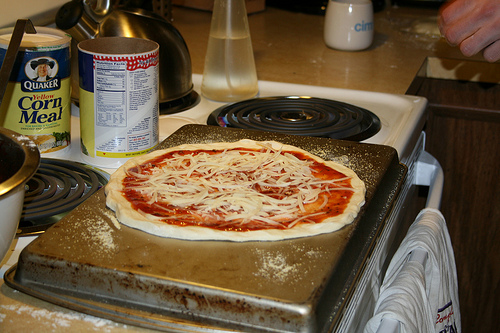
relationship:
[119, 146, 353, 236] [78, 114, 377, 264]
sauce on pizza.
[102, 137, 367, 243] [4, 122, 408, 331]
cheese on pan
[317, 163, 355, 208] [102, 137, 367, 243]
sauce on cheese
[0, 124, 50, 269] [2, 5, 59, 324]
bowl on left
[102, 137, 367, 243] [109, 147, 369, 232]
cheese on top of pizza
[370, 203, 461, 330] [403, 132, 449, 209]
towel over handle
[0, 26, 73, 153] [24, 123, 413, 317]
corn-meal sitting on stove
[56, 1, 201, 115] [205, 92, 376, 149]
kettle sitting on burner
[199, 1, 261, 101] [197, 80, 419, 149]
bottle sitting on stove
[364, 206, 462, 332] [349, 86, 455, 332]
towel hanging on oven door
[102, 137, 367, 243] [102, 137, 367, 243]
cheese on cheese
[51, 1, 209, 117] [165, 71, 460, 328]
kettle on stove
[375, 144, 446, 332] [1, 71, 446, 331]
handle on oven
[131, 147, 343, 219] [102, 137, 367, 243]
cheese on a cheese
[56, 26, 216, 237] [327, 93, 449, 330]
container on oven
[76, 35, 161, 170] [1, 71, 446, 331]
container on oven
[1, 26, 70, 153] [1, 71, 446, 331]
container on oven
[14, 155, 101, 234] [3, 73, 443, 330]
burner on stove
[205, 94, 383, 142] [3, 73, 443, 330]
burner on stove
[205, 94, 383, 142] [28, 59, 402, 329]
burner on stove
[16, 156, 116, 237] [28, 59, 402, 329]
burner on stove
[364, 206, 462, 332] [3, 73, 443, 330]
towel on stove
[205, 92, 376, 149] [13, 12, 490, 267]
burner on stove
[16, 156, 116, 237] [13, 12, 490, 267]
burner on stove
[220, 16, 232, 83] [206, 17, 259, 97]
straw in bottle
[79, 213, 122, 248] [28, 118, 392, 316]
flour on surface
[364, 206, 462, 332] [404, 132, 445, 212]
towel hanging on handle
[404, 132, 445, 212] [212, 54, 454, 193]
handle on stove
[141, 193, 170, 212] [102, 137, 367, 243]
sauce on cheese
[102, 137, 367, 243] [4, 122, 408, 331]
cheese sitting on bottom of pan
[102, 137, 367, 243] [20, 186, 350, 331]
cheese sitting on bottom of pan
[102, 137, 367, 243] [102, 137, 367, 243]
cheese of cheese